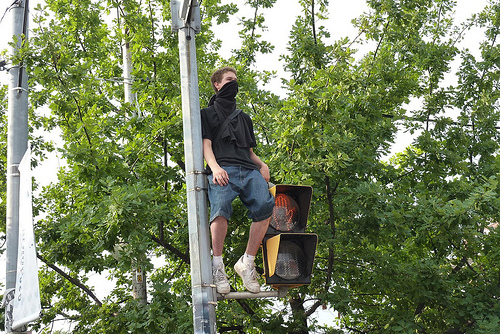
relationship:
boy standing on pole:
[198, 69, 276, 295] [178, 75, 252, 332]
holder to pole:
[260, 181, 313, 286] [175, 35, 218, 333]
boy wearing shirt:
[198, 69, 276, 295] [178, 85, 309, 175]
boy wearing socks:
[198, 69, 276, 295] [197, 234, 304, 305]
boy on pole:
[198, 69, 276, 295] [131, 22, 258, 314]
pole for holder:
[175, 35, 218, 333] [260, 181, 313, 286]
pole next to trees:
[120, 39, 245, 319] [35, 8, 473, 317]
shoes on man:
[210, 255, 263, 295] [174, 41, 344, 331]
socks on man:
[221, 240, 294, 282] [174, 41, 344, 331]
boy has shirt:
[153, 63, 335, 328] [177, 90, 329, 260]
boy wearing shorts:
[198, 69, 276, 295] [210, 160, 265, 220]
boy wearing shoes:
[198, 69, 276, 295] [213, 256, 273, 291]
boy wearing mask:
[198, 69, 276, 295] [217, 86, 254, 102]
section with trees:
[303, 11, 461, 222] [8, 3, 484, 322]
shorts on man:
[203, 163, 283, 225] [162, 58, 294, 284]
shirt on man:
[192, 100, 271, 163] [170, 56, 299, 304]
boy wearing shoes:
[198, 69, 276, 295] [210, 255, 263, 295]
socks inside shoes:
[206, 254, 258, 266] [210, 255, 263, 295]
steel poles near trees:
[14, 1, 237, 329] [35, 8, 473, 317]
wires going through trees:
[16, 47, 480, 160] [8, 3, 484, 322]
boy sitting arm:
[198, 69, 276, 295] [191, 108, 226, 190]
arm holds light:
[191, 108, 226, 190] [254, 183, 328, 283]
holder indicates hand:
[260, 181, 313, 286] [266, 193, 296, 234]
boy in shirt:
[198, 69, 276, 295] [185, 98, 277, 168]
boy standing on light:
[198, 69, 276, 295] [249, 180, 317, 301]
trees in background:
[35, 8, 473, 317] [23, 3, 480, 319]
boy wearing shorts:
[198, 69, 276, 295] [206, 170, 274, 221]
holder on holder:
[260, 181, 313, 286] [249, 172, 329, 266]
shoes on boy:
[195, 238, 298, 316] [184, 62, 289, 305]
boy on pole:
[198, 69, 276, 295] [154, 63, 233, 256]